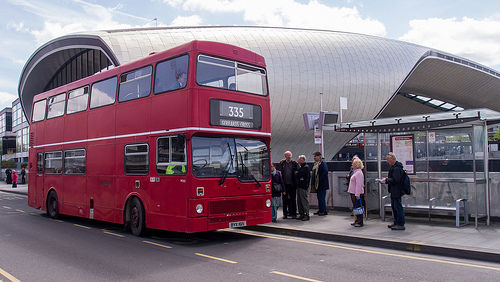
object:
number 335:
[226, 103, 247, 118]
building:
[0, 24, 497, 229]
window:
[191, 135, 238, 171]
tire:
[122, 194, 149, 236]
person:
[346, 151, 368, 227]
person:
[293, 153, 312, 219]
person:
[277, 150, 300, 220]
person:
[268, 157, 287, 223]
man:
[376, 153, 415, 230]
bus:
[25, 39, 273, 239]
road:
[0, 181, 500, 281]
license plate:
[227, 219, 249, 232]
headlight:
[264, 182, 274, 193]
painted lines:
[269, 271, 325, 282]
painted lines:
[191, 248, 241, 265]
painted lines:
[141, 237, 175, 249]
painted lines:
[102, 227, 127, 239]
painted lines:
[72, 221, 93, 231]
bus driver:
[164, 151, 189, 174]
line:
[1, 267, 19, 282]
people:
[307, 150, 332, 218]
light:
[265, 198, 275, 212]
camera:
[323, 112, 335, 126]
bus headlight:
[191, 202, 208, 216]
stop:
[315, 107, 500, 246]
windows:
[152, 135, 185, 179]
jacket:
[344, 169, 374, 198]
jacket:
[162, 160, 190, 180]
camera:
[303, 113, 318, 124]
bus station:
[320, 111, 500, 254]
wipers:
[218, 142, 240, 185]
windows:
[27, 96, 50, 125]